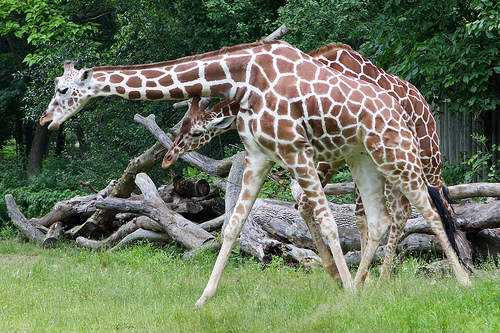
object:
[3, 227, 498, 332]
grass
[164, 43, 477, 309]
giraffe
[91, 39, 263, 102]
neck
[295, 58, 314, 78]
fur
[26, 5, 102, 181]
tree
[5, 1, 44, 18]
leaves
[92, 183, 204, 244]
logs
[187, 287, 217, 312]
feet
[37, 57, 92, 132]
head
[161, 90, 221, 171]
head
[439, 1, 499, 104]
trees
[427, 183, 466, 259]
hair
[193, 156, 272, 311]
leg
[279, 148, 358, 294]
leg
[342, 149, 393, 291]
leg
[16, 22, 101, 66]
branches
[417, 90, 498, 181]
fence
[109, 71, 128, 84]
spots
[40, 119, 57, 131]
mouth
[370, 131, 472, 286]
leg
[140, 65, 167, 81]
spot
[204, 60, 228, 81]
spot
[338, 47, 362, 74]
spot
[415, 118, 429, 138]
spot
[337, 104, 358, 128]
spot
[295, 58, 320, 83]
spot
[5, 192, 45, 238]
pile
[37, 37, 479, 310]
animals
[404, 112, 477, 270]
tail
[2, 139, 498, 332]
field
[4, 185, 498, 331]
ground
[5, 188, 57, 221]
bushes